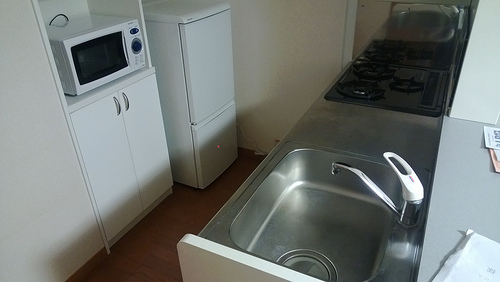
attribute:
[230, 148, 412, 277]
sink — silver, shiny, metal, small, stainless, steel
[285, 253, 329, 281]
hole — large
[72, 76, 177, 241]
cabinet — white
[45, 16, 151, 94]
microwave — white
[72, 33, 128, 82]
door — black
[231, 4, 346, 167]
wall — white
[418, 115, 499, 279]
counter — stainless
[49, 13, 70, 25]
cord — black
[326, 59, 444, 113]
stove — black, gas, small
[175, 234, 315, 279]
edge — white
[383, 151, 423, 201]
handle — white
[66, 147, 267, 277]
floor — red, brick, below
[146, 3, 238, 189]
fridge — small, little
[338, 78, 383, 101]
grill — black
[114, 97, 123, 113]
handle — silver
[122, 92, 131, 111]
handle — silver